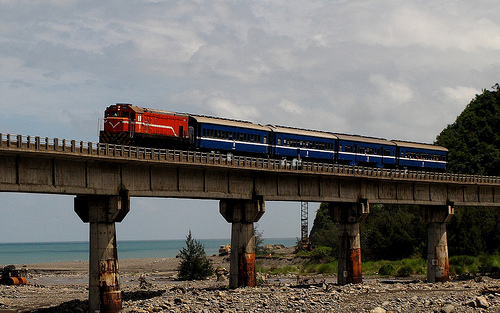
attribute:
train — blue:
[96, 99, 451, 177]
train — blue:
[99, 102, 450, 173]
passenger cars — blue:
[186, 111, 268, 156]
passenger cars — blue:
[267, 121, 337, 160]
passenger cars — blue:
[334, 130, 397, 165]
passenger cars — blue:
[393, 135, 448, 170]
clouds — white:
[0, 13, 499, 145]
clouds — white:
[235, 17, 445, 119]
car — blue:
[185, 109, 274, 159]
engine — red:
[95, 103, 190, 153]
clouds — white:
[181, 11, 396, 95]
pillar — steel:
[229, 219, 256, 288]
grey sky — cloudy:
[1, 0, 498, 241]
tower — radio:
[276, 187, 327, 275]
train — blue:
[334, 122, 393, 167]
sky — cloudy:
[0, 0, 498, 243]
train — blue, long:
[93, 96, 469, 181]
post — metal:
[216, 196, 266, 291]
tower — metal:
[299, 196, 356, 251]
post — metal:
[334, 192, 371, 282]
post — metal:
[75, 196, 132, 311]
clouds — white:
[356, 35, 427, 115]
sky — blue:
[296, 22, 493, 95]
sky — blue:
[12, 27, 458, 102]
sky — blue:
[10, 23, 164, 89]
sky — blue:
[10, 18, 95, 115]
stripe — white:
[200, 133, 455, 165]